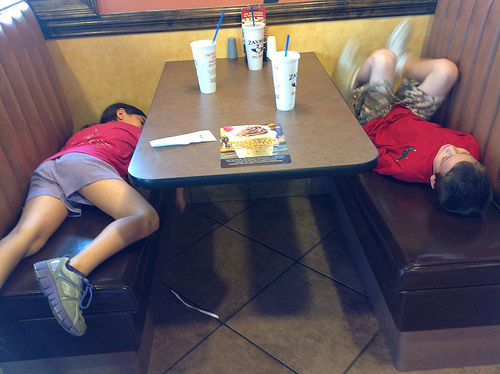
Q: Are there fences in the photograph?
A: No, there are no fences.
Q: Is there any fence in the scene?
A: No, there are no fences.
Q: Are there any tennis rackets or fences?
A: No, there are no fences or tennis rackets.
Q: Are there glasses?
A: No, there are no glasses.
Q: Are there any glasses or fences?
A: No, there are no glasses or fences.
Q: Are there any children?
A: Yes, there is a child.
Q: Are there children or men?
A: Yes, there is a child.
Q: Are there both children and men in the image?
A: No, there is a child but no men.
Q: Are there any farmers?
A: No, there are no farmers.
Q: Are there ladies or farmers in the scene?
A: No, there are no farmers or ladies.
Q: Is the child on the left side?
A: Yes, the child is on the left of the image.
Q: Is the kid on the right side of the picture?
A: No, the kid is on the left of the image.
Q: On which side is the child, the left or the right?
A: The child is on the left of the image.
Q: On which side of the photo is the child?
A: The child is on the left of the image.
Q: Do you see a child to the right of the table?
A: No, the child is to the left of the table.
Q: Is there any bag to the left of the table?
A: No, there is a child to the left of the table.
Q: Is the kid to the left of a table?
A: Yes, the kid is to the left of a table.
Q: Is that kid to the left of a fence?
A: No, the kid is to the left of a table.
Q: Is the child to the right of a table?
A: No, the child is to the left of a table.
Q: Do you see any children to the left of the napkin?
A: Yes, there is a child to the left of the napkin.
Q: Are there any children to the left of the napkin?
A: Yes, there is a child to the left of the napkin.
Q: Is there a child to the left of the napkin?
A: Yes, there is a child to the left of the napkin.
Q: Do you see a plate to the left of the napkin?
A: No, there is a child to the left of the napkin.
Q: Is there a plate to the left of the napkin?
A: No, there is a child to the left of the napkin.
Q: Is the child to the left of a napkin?
A: Yes, the child is to the left of a napkin.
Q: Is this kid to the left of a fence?
A: No, the kid is to the left of a napkin.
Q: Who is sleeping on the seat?
A: The child is sleeping on the seat.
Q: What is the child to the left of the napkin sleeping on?
A: The kid is sleeping on the seat.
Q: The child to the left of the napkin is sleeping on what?
A: The kid is sleeping on the seat.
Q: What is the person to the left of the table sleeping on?
A: The kid is sleeping on the seat.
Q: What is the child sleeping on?
A: The kid is sleeping on the seat.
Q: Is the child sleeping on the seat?
A: Yes, the child is sleeping on the seat.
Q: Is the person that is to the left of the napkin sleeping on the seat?
A: Yes, the child is sleeping on the seat.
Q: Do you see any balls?
A: No, there are no balls.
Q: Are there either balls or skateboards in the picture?
A: No, there are no balls or skateboards.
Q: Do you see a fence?
A: No, there are no fences.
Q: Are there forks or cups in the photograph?
A: Yes, there is a cup.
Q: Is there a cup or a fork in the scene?
A: Yes, there is a cup.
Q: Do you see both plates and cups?
A: No, there is a cup but no plates.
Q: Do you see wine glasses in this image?
A: No, there are no wine glasses.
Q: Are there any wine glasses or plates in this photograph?
A: No, there are no wine glasses or plates.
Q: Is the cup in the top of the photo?
A: Yes, the cup is in the top of the image.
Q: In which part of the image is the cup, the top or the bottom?
A: The cup is in the top of the image.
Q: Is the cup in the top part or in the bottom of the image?
A: The cup is in the top of the image.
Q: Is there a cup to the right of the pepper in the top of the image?
A: Yes, there is a cup to the right of the pepper.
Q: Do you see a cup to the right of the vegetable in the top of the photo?
A: Yes, there is a cup to the right of the pepper.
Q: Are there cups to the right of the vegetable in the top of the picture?
A: Yes, there is a cup to the right of the pepper.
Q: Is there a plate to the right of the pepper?
A: No, there is a cup to the right of the pepper.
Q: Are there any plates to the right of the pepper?
A: No, there is a cup to the right of the pepper.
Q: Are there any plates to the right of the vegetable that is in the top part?
A: No, there is a cup to the right of the pepper.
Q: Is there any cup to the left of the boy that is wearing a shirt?
A: Yes, there is a cup to the left of the boy.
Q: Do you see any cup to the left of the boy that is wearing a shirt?
A: Yes, there is a cup to the left of the boy.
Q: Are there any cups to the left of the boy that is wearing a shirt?
A: Yes, there is a cup to the left of the boy.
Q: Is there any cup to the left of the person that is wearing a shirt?
A: Yes, there is a cup to the left of the boy.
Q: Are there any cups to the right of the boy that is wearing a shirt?
A: No, the cup is to the left of the boy.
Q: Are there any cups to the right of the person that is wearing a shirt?
A: No, the cup is to the left of the boy.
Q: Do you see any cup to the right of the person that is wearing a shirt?
A: No, the cup is to the left of the boy.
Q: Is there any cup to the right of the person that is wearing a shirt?
A: No, the cup is to the left of the boy.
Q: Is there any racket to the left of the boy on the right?
A: No, there is a cup to the left of the boy.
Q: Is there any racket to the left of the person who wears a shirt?
A: No, there is a cup to the left of the boy.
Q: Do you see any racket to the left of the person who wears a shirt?
A: No, there is a cup to the left of the boy.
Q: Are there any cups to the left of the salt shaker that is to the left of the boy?
A: Yes, there is a cup to the left of the salt shaker.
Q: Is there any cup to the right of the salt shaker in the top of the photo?
A: No, the cup is to the left of the salt shaker.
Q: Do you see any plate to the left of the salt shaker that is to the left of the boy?
A: No, there is a cup to the left of the salt shaker.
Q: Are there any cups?
A: Yes, there is a cup.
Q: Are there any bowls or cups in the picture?
A: Yes, there is a cup.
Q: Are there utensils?
A: No, there are no utensils.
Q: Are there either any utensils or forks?
A: No, there are no utensils or forks.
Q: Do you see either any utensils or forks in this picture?
A: No, there are no utensils or forks.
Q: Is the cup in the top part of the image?
A: Yes, the cup is in the top of the image.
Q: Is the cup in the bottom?
A: No, the cup is in the top of the image.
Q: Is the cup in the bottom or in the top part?
A: The cup is in the top of the image.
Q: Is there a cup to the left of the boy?
A: Yes, there is a cup to the left of the boy.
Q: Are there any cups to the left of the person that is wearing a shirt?
A: Yes, there is a cup to the left of the boy.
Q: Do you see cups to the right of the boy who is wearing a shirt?
A: No, the cup is to the left of the boy.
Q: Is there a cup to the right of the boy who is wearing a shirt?
A: No, the cup is to the left of the boy.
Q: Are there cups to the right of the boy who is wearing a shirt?
A: No, the cup is to the left of the boy.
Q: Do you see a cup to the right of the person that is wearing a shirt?
A: No, the cup is to the left of the boy.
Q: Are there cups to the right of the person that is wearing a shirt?
A: No, the cup is to the left of the boy.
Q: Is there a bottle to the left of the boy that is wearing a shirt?
A: No, there is a cup to the left of the boy.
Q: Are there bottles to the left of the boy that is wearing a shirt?
A: No, there is a cup to the left of the boy.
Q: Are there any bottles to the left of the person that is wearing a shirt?
A: No, there is a cup to the left of the boy.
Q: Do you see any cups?
A: Yes, there is a cup.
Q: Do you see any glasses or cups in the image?
A: Yes, there is a cup.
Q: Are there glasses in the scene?
A: No, there are no glasses.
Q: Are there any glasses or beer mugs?
A: No, there are no glasses or beer mugs.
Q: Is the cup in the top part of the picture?
A: Yes, the cup is in the top of the image.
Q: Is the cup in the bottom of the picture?
A: No, the cup is in the top of the image.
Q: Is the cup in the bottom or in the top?
A: The cup is in the top of the image.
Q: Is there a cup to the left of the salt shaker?
A: Yes, there is a cup to the left of the salt shaker.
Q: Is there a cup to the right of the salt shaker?
A: No, the cup is to the left of the salt shaker.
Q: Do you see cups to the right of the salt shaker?
A: No, the cup is to the left of the salt shaker.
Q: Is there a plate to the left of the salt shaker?
A: No, there is a cup to the left of the salt shaker.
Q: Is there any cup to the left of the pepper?
A: Yes, there is a cup to the left of the pepper.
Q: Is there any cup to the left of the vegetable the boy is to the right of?
A: Yes, there is a cup to the left of the pepper.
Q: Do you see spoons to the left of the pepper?
A: No, there is a cup to the left of the pepper.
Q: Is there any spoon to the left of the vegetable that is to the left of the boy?
A: No, there is a cup to the left of the pepper.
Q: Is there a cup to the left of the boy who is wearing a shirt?
A: Yes, there is a cup to the left of the boy.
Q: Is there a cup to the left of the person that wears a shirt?
A: Yes, there is a cup to the left of the boy.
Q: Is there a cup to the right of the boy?
A: No, the cup is to the left of the boy.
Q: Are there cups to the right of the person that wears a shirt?
A: No, the cup is to the left of the boy.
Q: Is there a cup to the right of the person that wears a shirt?
A: No, the cup is to the left of the boy.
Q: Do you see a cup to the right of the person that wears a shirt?
A: No, the cup is to the left of the boy.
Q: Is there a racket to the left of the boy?
A: No, there is a cup to the left of the boy.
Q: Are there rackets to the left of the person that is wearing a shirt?
A: No, there is a cup to the left of the boy.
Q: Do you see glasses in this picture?
A: No, there are no glasses.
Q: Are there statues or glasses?
A: No, there are no glasses or statues.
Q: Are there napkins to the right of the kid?
A: Yes, there is a napkin to the right of the kid.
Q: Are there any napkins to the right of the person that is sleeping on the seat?
A: Yes, there is a napkin to the right of the kid.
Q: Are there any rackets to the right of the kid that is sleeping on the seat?
A: No, there is a napkin to the right of the kid.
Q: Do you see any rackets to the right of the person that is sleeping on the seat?
A: No, there is a napkin to the right of the kid.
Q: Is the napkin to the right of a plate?
A: No, the napkin is to the right of the kid.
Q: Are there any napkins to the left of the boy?
A: Yes, there is a napkin to the left of the boy.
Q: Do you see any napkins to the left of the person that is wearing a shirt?
A: Yes, there is a napkin to the left of the boy.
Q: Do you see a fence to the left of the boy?
A: No, there is a napkin to the left of the boy.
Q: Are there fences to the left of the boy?
A: No, there is a napkin to the left of the boy.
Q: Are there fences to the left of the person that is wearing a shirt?
A: No, there is a napkin to the left of the boy.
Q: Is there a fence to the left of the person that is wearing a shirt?
A: No, there is a napkin to the left of the boy.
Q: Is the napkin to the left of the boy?
A: Yes, the napkin is to the left of the boy.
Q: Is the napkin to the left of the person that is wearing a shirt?
A: Yes, the napkin is to the left of the boy.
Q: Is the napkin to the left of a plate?
A: No, the napkin is to the left of the boy.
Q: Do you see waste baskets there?
A: No, there are no waste baskets.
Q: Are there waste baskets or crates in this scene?
A: No, there are no waste baskets or crates.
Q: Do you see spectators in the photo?
A: No, there are no spectators.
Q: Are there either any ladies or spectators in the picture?
A: No, there are no spectators or ladies.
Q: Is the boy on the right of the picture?
A: Yes, the boy is on the right of the image.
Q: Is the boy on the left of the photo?
A: No, the boy is on the right of the image.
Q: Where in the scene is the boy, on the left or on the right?
A: The boy is on the right of the image.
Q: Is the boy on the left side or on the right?
A: The boy is on the right of the image.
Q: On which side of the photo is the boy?
A: The boy is on the right of the image.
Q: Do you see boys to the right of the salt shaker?
A: Yes, there is a boy to the right of the salt shaker.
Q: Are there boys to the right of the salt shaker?
A: Yes, there is a boy to the right of the salt shaker.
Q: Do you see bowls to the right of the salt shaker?
A: No, there is a boy to the right of the salt shaker.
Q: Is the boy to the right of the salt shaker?
A: Yes, the boy is to the right of the salt shaker.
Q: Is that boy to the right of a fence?
A: No, the boy is to the right of the salt shaker.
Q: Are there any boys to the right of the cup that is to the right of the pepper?
A: Yes, there is a boy to the right of the cup.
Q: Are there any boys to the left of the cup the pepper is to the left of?
A: No, the boy is to the right of the cup.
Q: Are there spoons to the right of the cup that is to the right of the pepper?
A: No, there is a boy to the right of the cup.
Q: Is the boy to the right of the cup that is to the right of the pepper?
A: Yes, the boy is to the right of the cup.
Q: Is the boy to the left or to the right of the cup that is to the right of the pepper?
A: The boy is to the right of the cup.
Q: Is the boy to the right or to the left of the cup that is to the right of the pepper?
A: The boy is to the right of the cup.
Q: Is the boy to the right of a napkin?
A: Yes, the boy is to the right of a napkin.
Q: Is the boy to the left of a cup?
A: No, the boy is to the right of a cup.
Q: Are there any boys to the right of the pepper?
A: Yes, there is a boy to the right of the pepper.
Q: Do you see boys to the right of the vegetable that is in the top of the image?
A: Yes, there is a boy to the right of the pepper.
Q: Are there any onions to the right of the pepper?
A: No, there is a boy to the right of the pepper.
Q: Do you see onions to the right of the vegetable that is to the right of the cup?
A: No, there is a boy to the right of the pepper.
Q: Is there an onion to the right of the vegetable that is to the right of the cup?
A: No, there is a boy to the right of the pepper.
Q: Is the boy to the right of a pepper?
A: Yes, the boy is to the right of a pepper.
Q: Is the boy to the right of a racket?
A: No, the boy is to the right of a pepper.